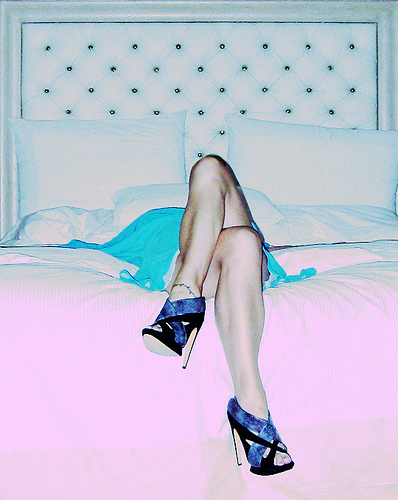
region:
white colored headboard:
[34, 21, 394, 117]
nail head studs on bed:
[70, 45, 340, 96]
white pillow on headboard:
[6, 105, 193, 249]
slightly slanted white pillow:
[235, 104, 390, 224]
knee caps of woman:
[181, 144, 280, 297]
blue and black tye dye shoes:
[158, 280, 220, 360]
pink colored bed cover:
[44, 316, 232, 495]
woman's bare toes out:
[269, 444, 293, 475]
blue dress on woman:
[101, 204, 198, 290]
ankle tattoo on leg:
[176, 270, 208, 304]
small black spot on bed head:
[99, 100, 142, 120]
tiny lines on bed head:
[176, 45, 245, 72]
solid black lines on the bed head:
[5, 6, 145, 40]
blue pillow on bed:
[1, 94, 197, 186]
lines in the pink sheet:
[323, 268, 396, 328]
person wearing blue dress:
[108, 217, 177, 267]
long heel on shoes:
[216, 415, 248, 468]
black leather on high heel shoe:
[216, 414, 322, 474]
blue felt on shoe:
[223, 393, 287, 449]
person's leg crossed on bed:
[125, 155, 272, 297]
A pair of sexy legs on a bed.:
[132, 145, 307, 492]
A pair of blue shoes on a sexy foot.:
[201, 393, 290, 483]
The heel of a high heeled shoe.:
[226, 417, 239, 463]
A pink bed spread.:
[89, 386, 149, 449]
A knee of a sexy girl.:
[191, 145, 233, 204]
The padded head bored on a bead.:
[18, 15, 376, 118]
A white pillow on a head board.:
[7, 102, 199, 245]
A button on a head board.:
[302, 80, 316, 95]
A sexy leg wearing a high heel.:
[196, 226, 284, 496]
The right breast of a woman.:
[130, 204, 172, 249]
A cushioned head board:
[0, 51, 394, 97]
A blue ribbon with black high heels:
[212, 390, 325, 483]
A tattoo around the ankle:
[171, 277, 205, 302]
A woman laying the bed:
[74, 188, 370, 468]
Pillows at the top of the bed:
[11, 100, 384, 233]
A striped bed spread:
[5, 243, 396, 463]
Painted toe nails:
[269, 451, 300, 470]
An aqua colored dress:
[65, 174, 183, 295]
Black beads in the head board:
[218, 32, 286, 80]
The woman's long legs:
[160, 147, 323, 471]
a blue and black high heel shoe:
[224, 383, 298, 483]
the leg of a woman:
[188, 211, 280, 423]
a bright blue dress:
[56, 197, 319, 310]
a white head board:
[1, 2, 396, 189]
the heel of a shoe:
[180, 325, 203, 369]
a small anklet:
[168, 277, 199, 300]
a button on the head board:
[195, 107, 205, 117]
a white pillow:
[109, 168, 285, 247]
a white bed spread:
[2, 240, 397, 499]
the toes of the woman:
[270, 445, 297, 468]